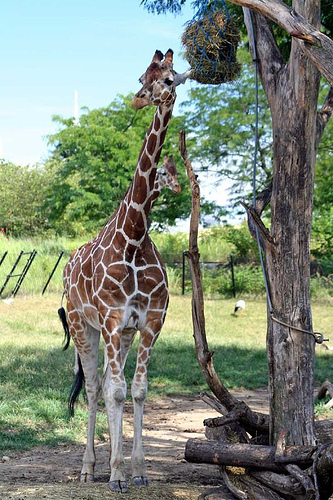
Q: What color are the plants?
A: Green.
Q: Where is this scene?
A: Park.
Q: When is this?
A: Daytime.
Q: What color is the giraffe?
A: Spotted brown.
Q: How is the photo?
A: Clear.